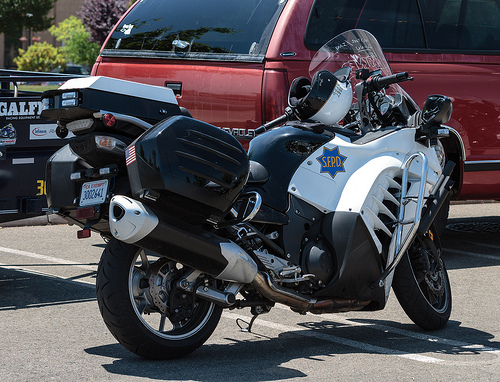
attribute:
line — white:
[2, 247, 494, 372]